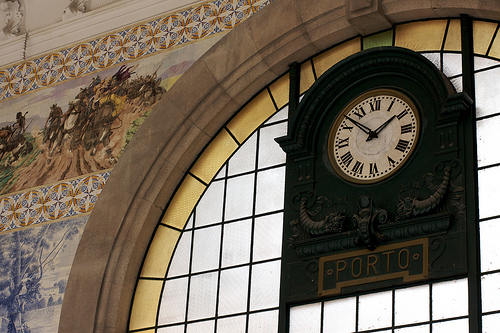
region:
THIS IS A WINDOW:
[46, 5, 494, 331]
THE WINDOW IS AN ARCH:
[48, 0, 498, 330]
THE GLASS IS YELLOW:
[136, 276, 160, 331]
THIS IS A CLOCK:
[327, 86, 432, 201]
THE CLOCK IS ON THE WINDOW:
[323, 90, 418, 190]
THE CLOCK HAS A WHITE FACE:
[315, 86, 422, 201]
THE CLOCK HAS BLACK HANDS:
[330, 84, 420, 197]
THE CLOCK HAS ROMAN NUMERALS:
[324, 85, 429, 191]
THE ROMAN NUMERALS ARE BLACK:
[322, 89, 420, 187]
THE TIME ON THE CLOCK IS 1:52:
[336, 98, 412, 171]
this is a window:
[53, 3, 498, 331]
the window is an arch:
[58, 0, 499, 325]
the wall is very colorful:
[1, 0, 272, 329]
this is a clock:
[326, 75, 414, 205]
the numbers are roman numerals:
[316, 90, 413, 200]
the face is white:
[318, 87, 414, 187]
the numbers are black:
[323, 79, 418, 193]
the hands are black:
[325, 90, 417, 178]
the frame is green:
[280, 43, 482, 308]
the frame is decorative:
[273, 49, 496, 314]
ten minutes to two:
[344, 107, 406, 137]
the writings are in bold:
[322, 248, 427, 290]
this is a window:
[227, 193, 272, 330]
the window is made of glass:
[209, 217, 246, 283]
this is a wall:
[20, 13, 112, 127]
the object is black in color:
[438, 105, 458, 158]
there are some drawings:
[23, 58, 128, 156]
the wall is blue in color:
[56, 262, 69, 272]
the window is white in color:
[225, 275, 240, 301]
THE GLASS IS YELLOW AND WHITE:
[123, 10, 496, 332]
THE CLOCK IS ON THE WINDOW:
[272, 12, 485, 332]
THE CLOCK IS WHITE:
[331, 80, 418, 185]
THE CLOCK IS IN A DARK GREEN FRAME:
[270, 40, 497, 309]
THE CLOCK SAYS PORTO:
[326, 244, 418, 299]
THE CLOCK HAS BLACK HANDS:
[341, 108, 402, 146]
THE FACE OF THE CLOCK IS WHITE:
[322, 83, 422, 190]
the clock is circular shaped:
[323, 95, 419, 191]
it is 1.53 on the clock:
[331, 93, 423, 184]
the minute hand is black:
[336, 108, 408, 148]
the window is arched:
[77, 6, 497, 330]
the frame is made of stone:
[158, 78, 222, 138]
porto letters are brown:
[326, 240, 433, 298]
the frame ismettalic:
[290, 64, 487, 307]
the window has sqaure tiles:
[183, 200, 271, 321]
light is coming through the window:
[209, 213, 262, 329]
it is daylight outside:
[196, 210, 266, 312]